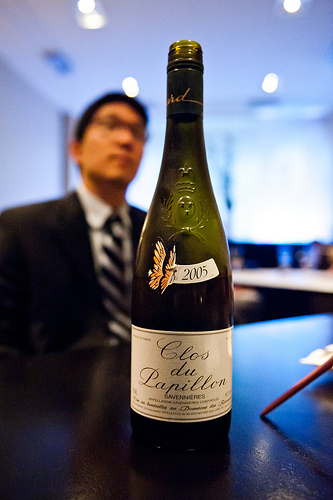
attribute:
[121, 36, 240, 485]
bottle — wine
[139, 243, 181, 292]
an insect — green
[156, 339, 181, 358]
letter — black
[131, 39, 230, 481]
bottle — wine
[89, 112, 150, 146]
glasses — black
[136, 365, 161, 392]
letter — black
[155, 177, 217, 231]
imprint — green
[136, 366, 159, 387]
letter — black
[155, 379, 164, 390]
letter — black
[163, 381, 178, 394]
letter — black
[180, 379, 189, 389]
letter — black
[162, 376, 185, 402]
letter — black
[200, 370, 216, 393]
letter — black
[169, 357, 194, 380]
letter — black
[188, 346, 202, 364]
letter — black